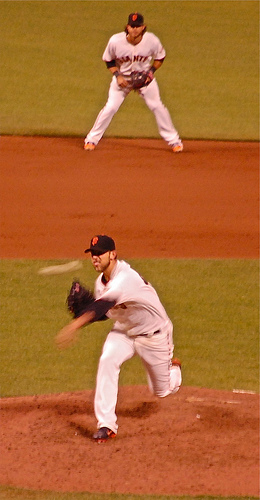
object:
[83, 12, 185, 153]
baseball player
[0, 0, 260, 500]
field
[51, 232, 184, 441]
baseball player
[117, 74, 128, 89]
hand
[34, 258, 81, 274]
ball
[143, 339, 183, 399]
leg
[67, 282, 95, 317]
glove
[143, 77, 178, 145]
leg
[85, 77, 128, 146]
leg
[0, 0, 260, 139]
grass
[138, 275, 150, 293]
back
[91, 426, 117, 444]
foot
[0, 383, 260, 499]
mound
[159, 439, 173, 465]
dirt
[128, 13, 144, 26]
hat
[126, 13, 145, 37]
head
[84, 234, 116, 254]
hat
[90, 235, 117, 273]
head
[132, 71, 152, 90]
glove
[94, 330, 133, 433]
leg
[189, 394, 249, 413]
plate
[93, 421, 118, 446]
shoe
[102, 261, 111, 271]
beard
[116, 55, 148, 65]
word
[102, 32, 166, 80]
jersey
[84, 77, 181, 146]
pants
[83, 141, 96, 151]
sneaker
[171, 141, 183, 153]
sneaker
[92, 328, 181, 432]
pants